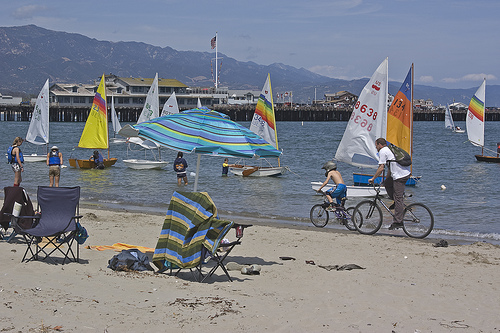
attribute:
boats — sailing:
[5, 112, 429, 208]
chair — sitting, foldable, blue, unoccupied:
[15, 175, 93, 267]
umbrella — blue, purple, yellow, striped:
[120, 79, 293, 223]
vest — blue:
[0, 124, 119, 202]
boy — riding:
[290, 146, 377, 221]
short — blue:
[321, 183, 353, 207]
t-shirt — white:
[366, 136, 416, 190]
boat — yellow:
[57, 66, 127, 177]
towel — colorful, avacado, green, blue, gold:
[148, 184, 224, 279]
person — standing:
[217, 152, 291, 183]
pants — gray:
[372, 169, 419, 232]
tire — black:
[342, 196, 390, 238]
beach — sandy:
[0, 175, 499, 332]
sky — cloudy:
[196, 2, 499, 125]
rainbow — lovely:
[442, 60, 498, 169]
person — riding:
[349, 135, 439, 252]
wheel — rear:
[394, 194, 441, 244]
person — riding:
[303, 163, 363, 236]